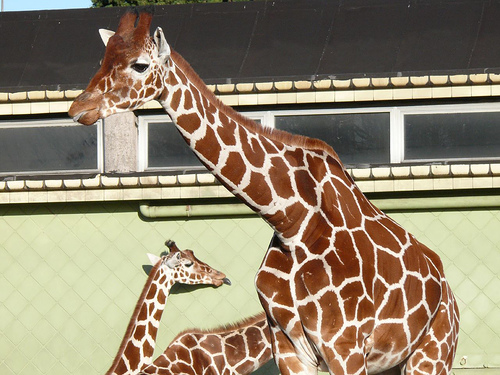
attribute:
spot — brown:
[220, 149, 247, 188]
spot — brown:
[243, 169, 272, 209]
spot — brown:
[371, 246, 406, 286]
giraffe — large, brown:
[61, 9, 461, 373]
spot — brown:
[191, 122, 221, 168]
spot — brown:
[400, 272, 425, 312]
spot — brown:
[133, 321, 148, 340]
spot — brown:
[421, 276, 443, 317]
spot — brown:
[329, 282, 367, 320]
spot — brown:
[357, 219, 403, 255]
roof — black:
[3, 6, 472, 191]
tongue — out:
[212, 268, 239, 290]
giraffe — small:
[99, 249, 233, 372]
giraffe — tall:
[95, 236, 241, 373]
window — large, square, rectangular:
[394, 105, 484, 165]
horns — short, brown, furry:
[106, 9, 152, 43]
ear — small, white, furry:
[146, 24, 171, 63]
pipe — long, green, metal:
[133, 191, 482, 219]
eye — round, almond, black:
[182, 254, 196, 270]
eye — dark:
[125, 58, 152, 78]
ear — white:
[91, 27, 117, 48]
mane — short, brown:
[170, 49, 340, 166]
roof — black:
[3, 6, 483, 108]